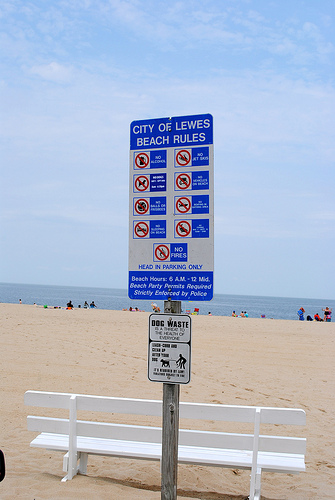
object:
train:
[12, 291, 90, 372]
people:
[232, 310, 238, 317]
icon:
[160, 353, 188, 369]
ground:
[296, 76, 312, 104]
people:
[297, 307, 306, 322]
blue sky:
[2, 2, 334, 113]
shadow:
[77, 470, 249, 500]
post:
[127, 113, 215, 302]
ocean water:
[0, 282, 335, 320]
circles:
[132, 146, 210, 263]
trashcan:
[0, 448, 5, 483]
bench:
[24, 389, 307, 500]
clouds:
[0, 0, 335, 245]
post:
[146, 312, 192, 385]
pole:
[160, 300, 181, 499]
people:
[90, 301, 98, 309]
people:
[83, 301, 89, 309]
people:
[66, 300, 73, 310]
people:
[19, 299, 22, 304]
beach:
[0, 303, 333, 498]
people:
[322, 306, 333, 322]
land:
[1, 309, 333, 499]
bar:
[160, 382, 180, 498]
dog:
[160, 358, 171, 368]